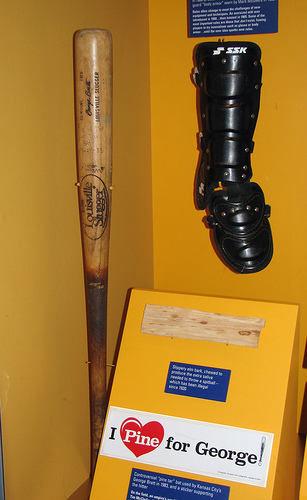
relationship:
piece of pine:
[43, 42, 84, 83] [64, 31, 141, 166]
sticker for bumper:
[112, 387, 300, 475] [59, 357, 299, 487]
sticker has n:
[112, 387, 300, 475] [133, 427, 155, 449]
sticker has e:
[112, 387, 300, 475] [141, 437, 163, 458]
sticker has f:
[112, 387, 300, 475] [157, 431, 172, 459]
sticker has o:
[112, 387, 300, 475] [175, 442, 181, 460]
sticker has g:
[112, 387, 300, 475] [192, 435, 213, 463]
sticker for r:
[112, 387, 300, 475] [180, 437, 197, 469]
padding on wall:
[163, 54, 305, 254] [140, 62, 271, 244]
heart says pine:
[108, 401, 166, 478] [113, 413, 177, 464]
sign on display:
[173, 0, 303, 32] [110, 328, 262, 492]